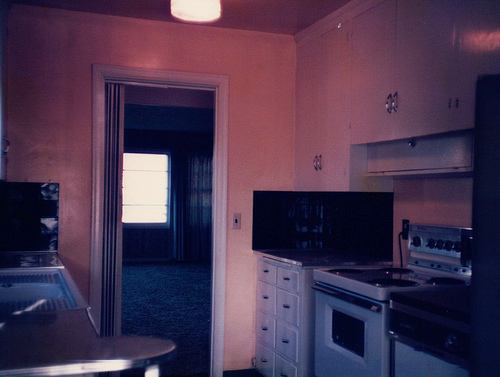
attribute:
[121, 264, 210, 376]
ground has carpet — blue, bare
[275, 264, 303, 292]
drawer is closed — white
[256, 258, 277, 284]
drawer is kitchen — white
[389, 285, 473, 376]
dishwasher is auto — old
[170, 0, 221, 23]
lights for kitchen — circular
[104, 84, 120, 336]
door is pleated — sliding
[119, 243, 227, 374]
ground — carpeted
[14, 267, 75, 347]
sink — metalic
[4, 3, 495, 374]
kitchen — clean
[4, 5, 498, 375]
room — kitchen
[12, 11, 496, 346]
walls — pink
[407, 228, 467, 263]
knobs — black 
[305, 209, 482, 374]
range — white , electric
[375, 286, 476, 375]
dishwasher — automatic 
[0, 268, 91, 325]
single basin — single , white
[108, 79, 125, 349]
door — accordion pleated